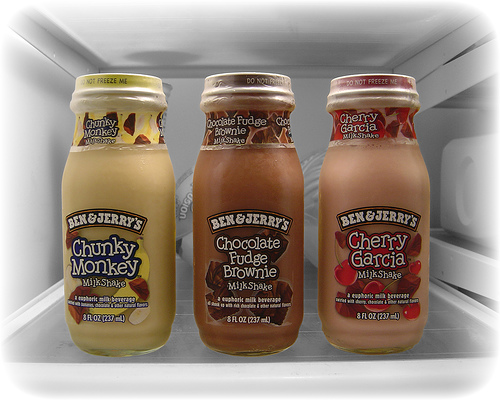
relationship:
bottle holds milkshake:
[61, 73, 176, 357] [62, 113, 176, 351]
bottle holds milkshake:
[190, 70, 305, 357] [193, 103, 306, 353]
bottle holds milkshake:
[317, 72, 428, 351] [319, 103, 431, 352]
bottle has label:
[61, 73, 176, 357] [64, 207, 151, 328]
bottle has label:
[317, 72, 428, 351] [334, 205, 422, 321]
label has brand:
[64, 207, 151, 328] [66, 207, 149, 242]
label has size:
[64, 207, 151, 328] [81, 313, 126, 325]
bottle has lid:
[61, 73, 176, 357] [72, 72, 165, 98]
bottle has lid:
[190, 70, 305, 357] [201, 71, 293, 96]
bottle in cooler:
[190, 70, 305, 357] [6, 4, 496, 386]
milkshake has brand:
[62, 113, 176, 351] [66, 207, 149, 242]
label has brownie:
[204, 209, 293, 325] [251, 280, 293, 326]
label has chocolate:
[334, 205, 422, 321] [395, 271, 421, 306]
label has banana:
[64, 207, 151, 328] [88, 237, 149, 318]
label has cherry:
[334, 205, 422, 321] [333, 240, 358, 286]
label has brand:
[204, 209, 293, 325] [208, 209, 295, 239]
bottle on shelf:
[61, 73, 176, 357] [5, 252, 497, 376]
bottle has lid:
[317, 72, 428, 351] [328, 73, 422, 100]